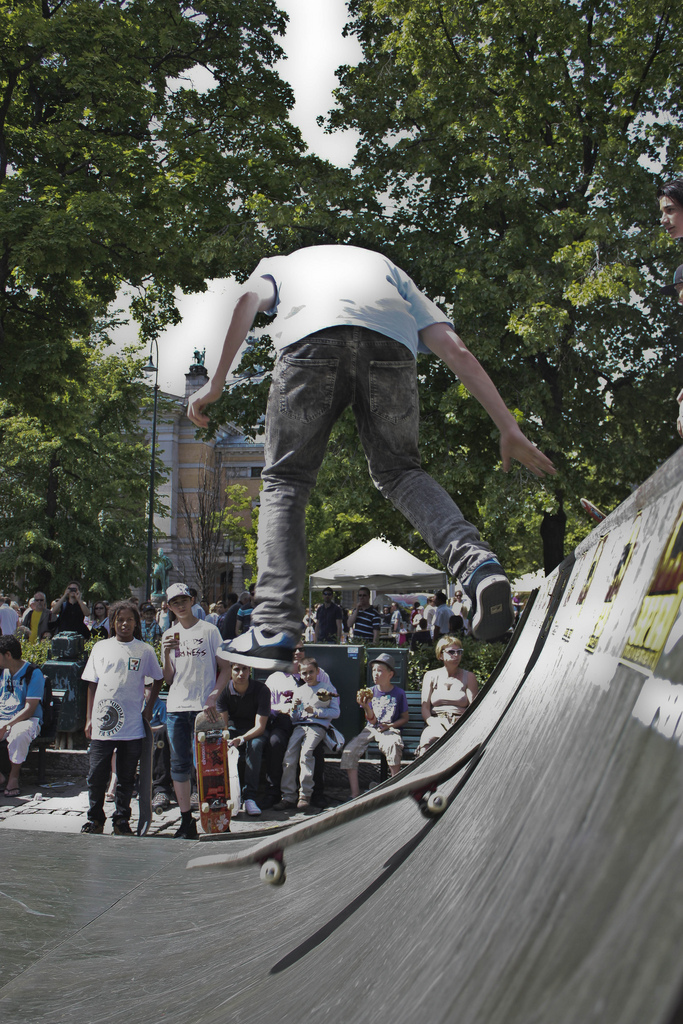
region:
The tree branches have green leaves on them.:
[13, 40, 162, 268]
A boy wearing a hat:
[326, 633, 408, 792]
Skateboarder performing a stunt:
[146, 154, 580, 931]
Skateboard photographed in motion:
[130, 682, 549, 923]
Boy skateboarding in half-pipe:
[26, 202, 664, 1009]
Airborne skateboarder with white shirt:
[139, 187, 582, 703]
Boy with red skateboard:
[141, 575, 250, 836]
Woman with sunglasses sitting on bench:
[418, 629, 487, 756]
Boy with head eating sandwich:
[335, 643, 403, 797]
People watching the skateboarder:
[45, 570, 412, 851]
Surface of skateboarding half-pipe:
[493, 737, 674, 1011]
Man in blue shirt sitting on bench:
[1, 640, 49, 798]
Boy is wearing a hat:
[141, 552, 245, 708]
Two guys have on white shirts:
[67, 564, 236, 777]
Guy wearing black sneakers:
[201, 543, 566, 709]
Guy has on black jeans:
[156, 275, 541, 722]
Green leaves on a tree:
[32, 27, 266, 287]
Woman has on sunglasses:
[415, 622, 487, 762]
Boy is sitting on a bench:
[360, 654, 431, 798]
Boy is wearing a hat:
[360, 622, 402, 735]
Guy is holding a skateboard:
[144, 567, 255, 918]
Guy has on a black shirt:
[209, 642, 284, 751]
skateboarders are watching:
[97, 587, 231, 849]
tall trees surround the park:
[38, 78, 186, 502]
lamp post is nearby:
[103, 338, 168, 522]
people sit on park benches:
[229, 638, 472, 774]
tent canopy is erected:
[258, 514, 470, 644]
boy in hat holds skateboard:
[128, 571, 256, 818]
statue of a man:
[147, 537, 183, 607]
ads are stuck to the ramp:
[538, 565, 678, 659]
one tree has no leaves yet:
[196, 524, 242, 602]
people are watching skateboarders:
[18, 579, 388, 631]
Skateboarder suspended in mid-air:
[108, 211, 569, 914]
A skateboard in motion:
[149, 739, 530, 926]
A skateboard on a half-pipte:
[9, 676, 662, 1002]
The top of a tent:
[303, 519, 453, 604]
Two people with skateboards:
[72, 573, 234, 842]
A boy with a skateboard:
[149, 573, 242, 841]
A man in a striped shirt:
[350, 597, 385, 649]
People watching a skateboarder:
[21, 546, 337, 881]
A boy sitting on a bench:
[345, 636, 419, 793]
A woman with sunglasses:
[416, 627, 483, 768]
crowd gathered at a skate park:
[13, 568, 475, 821]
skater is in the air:
[198, 229, 530, 680]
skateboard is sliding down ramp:
[188, 729, 498, 899]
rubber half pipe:
[47, 463, 672, 1019]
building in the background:
[139, 380, 263, 610]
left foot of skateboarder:
[204, 623, 309, 681]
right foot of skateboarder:
[452, 563, 528, 672]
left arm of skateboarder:
[180, 278, 279, 441]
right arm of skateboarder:
[421, 306, 565, 490]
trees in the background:
[0, 331, 144, 600]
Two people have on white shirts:
[95, 580, 221, 733]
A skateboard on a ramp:
[165, 773, 553, 897]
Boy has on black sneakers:
[171, 573, 582, 714]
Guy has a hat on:
[152, 556, 218, 669]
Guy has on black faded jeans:
[188, 264, 522, 636]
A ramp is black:
[69, 788, 650, 994]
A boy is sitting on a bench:
[346, 651, 426, 787]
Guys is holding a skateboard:
[148, 574, 263, 848]